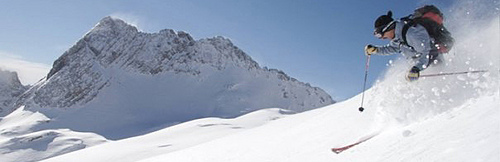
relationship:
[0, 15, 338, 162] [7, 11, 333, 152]
hill covered mountain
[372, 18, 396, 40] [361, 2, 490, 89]
goggles on skier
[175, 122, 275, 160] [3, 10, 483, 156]
snow covered ski slope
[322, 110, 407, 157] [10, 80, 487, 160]
ski on top of snow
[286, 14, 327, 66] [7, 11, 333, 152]
sky above mountain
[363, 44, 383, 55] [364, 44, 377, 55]
glove on glove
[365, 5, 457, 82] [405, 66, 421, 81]
man has gloves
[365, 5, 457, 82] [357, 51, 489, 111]
man has poles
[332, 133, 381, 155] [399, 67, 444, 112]
ski on feet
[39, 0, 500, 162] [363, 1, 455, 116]
snow tossed up by skier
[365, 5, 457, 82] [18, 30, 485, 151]
man skiing down hill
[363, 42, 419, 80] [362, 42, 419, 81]
gloves on hands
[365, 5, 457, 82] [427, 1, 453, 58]
man has backpack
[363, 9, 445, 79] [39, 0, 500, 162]
man skiing on snow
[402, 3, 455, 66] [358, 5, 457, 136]
backpack on man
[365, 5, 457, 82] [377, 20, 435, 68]
man wearing jacket